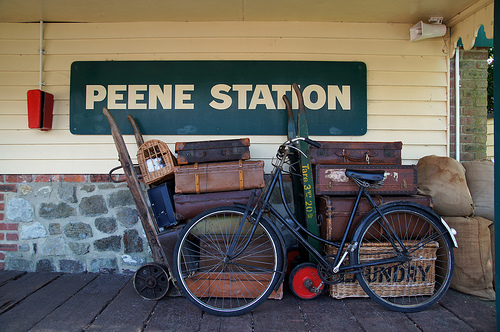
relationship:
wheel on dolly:
[132, 260, 171, 300] [99, 106, 182, 301]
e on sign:
[105, 82, 125, 110] [63, 51, 375, 140]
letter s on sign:
[207, 80, 234, 113] [66, 57, 369, 136]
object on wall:
[24, 87, 59, 131] [0, 24, 453, 174]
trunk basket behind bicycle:
[320, 235, 438, 302] [167, 138, 460, 317]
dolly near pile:
[97, 103, 188, 300] [134, 127, 291, 300]